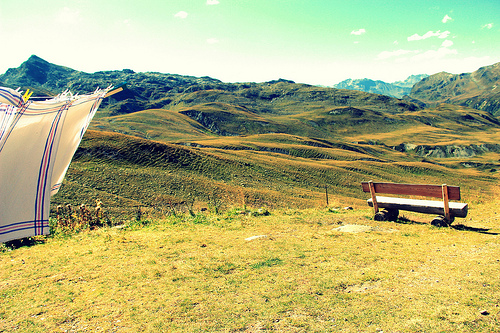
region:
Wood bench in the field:
[353, 176, 479, 229]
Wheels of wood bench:
[363, 210, 464, 230]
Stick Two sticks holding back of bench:
[363, 176, 453, 218]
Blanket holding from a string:
[2, 82, 123, 252]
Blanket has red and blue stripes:
[2, 75, 112, 257]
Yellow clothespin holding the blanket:
[10, 85, 36, 106]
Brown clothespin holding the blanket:
[100, 80, 125, 102]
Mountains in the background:
[0, 31, 497, 109]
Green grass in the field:
[74, 142, 498, 331]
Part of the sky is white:
[3, 53, 488, 76]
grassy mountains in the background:
[0, 66, 498, 163]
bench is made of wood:
[360, 179, 469, 226]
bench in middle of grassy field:
[362, 181, 468, 218]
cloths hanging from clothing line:
[0, 66, 112, 242]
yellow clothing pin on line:
[19, 89, 34, 104]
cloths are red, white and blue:
[0, 68, 102, 246]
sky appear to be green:
[0, 0, 497, 65]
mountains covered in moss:
[0, 54, 498, 116]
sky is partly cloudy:
[2, 0, 498, 68]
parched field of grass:
[0, 207, 499, 329]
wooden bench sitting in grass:
[362, 176, 469, 226]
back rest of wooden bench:
[360, 179, 465, 198]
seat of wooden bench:
[368, 194, 469, 219]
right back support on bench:
[439, 182, 452, 227]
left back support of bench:
[366, 178, 382, 218]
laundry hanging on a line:
[2, 77, 114, 244]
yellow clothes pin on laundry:
[16, 87, 36, 107]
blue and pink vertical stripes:
[33, 102, 69, 240]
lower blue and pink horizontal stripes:
[0, 218, 55, 236]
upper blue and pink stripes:
[1, 83, 107, 119]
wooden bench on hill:
[307, 146, 465, 242]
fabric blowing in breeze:
[6, 62, 126, 252]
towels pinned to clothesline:
[5, 75, 105, 250]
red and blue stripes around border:
[6, 85, 66, 241]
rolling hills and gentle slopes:
[165, 110, 385, 195]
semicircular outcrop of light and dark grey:
[375, 115, 485, 165]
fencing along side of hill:
[50, 175, 415, 231]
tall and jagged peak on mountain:
[10, 40, 85, 95]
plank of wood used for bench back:
[355, 167, 470, 237]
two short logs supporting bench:
[350, 161, 472, 243]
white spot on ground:
[241, 227, 284, 244]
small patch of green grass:
[230, 247, 295, 277]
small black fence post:
[306, 180, 341, 211]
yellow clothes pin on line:
[22, 85, 48, 115]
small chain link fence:
[113, 178, 288, 231]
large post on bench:
[360, 171, 388, 224]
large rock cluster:
[398, 130, 497, 177]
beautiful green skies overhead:
[281, 5, 377, 33]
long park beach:
[354, 157, 476, 237]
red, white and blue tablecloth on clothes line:
[10, 82, 138, 260]